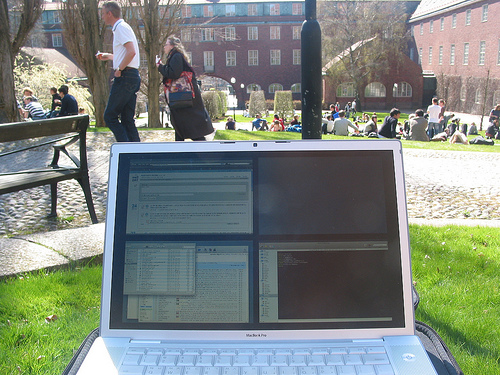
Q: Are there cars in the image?
A: No, there are no cars.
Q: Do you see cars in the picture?
A: No, there are no cars.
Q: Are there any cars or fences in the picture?
A: No, there are no cars or fences.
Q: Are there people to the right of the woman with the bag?
A: Yes, there is a person to the right of the woman.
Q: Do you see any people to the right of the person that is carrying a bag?
A: Yes, there is a person to the right of the woman.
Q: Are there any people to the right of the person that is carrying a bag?
A: Yes, there is a person to the right of the woman.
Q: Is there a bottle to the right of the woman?
A: No, there is a person to the right of the woman.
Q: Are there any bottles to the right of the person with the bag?
A: No, there is a person to the right of the woman.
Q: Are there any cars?
A: No, there are no cars.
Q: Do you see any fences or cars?
A: No, there are no cars or fences.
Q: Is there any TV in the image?
A: No, there are no televisions.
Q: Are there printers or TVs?
A: No, there are no TVs or printers.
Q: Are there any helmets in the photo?
A: No, there are no helmets.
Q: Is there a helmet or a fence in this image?
A: No, there are no helmets or fences.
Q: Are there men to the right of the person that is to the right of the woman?
A: Yes, there is a man to the right of the person.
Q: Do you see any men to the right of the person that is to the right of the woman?
A: Yes, there is a man to the right of the person.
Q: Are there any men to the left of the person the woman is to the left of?
A: No, the man is to the right of the person.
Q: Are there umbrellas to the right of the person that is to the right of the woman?
A: No, there is a man to the right of the person.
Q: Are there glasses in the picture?
A: No, there are no glasses.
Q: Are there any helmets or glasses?
A: No, there are no glasses or helmets.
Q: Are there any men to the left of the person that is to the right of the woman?
A: No, the man is to the right of the person.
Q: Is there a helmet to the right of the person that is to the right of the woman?
A: No, there is a man to the right of the person.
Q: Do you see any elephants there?
A: Yes, there is an elephant.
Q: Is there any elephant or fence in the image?
A: Yes, there is an elephant.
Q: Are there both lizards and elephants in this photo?
A: No, there is an elephant but no lizards.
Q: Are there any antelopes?
A: No, there are no antelopes.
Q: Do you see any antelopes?
A: No, there are no antelopes.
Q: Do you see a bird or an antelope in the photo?
A: No, there are no antelopes or birds.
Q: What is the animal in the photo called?
A: The animal is an elephant.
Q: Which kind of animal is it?
A: The animal is an elephant.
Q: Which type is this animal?
A: This is an elephant.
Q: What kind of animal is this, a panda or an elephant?
A: This is an elephant.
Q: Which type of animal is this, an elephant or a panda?
A: This is an elephant.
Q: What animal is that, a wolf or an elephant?
A: That is an elephant.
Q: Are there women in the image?
A: Yes, there is a woman.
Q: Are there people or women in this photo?
A: Yes, there is a woman.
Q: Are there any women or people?
A: Yes, there is a woman.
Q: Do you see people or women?
A: Yes, there is a woman.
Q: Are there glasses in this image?
A: No, there are no glasses.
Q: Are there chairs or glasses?
A: No, there are no glasses or chairs.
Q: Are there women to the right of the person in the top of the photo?
A: Yes, there is a woman to the right of the person.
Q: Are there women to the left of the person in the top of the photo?
A: No, the woman is to the right of the person.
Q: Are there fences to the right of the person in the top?
A: No, there is a woman to the right of the person.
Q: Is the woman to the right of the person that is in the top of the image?
A: Yes, the woman is to the right of the person.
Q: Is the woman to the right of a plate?
A: No, the woman is to the right of the person.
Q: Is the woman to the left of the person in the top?
A: No, the woman is to the right of the person.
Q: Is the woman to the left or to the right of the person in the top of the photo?
A: The woman is to the right of the person.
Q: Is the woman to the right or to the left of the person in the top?
A: The woman is to the right of the person.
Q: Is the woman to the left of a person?
A: Yes, the woman is to the left of a person.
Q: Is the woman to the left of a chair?
A: No, the woman is to the left of a person.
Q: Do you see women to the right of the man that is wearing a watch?
A: Yes, there is a woman to the right of the man.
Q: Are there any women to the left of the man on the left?
A: No, the woman is to the right of the man.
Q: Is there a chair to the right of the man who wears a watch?
A: No, there is a woman to the right of the man.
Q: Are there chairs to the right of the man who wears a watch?
A: No, there is a woman to the right of the man.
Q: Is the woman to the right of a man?
A: Yes, the woman is to the right of a man.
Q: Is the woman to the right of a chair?
A: No, the woman is to the right of a man.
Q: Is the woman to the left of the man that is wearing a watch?
A: No, the woman is to the right of the man.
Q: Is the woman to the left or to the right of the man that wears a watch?
A: The woman is to the right of the man.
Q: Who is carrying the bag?
A: The woman is carrying the bag.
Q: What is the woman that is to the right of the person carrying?
A: The woman is carrying a bag.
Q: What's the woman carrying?
A: The woman is carrying a bag.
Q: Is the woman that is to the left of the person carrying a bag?
A: Yes, the woman is carrying a bag.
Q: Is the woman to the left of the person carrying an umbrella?
A: No, the woman is carrying a bag.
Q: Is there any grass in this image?
A: Yes, there is grass.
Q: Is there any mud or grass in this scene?
A: Yes, there is grass.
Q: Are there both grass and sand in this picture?
A: No, there is grass but no sand.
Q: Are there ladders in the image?
A: No, there are no ladders.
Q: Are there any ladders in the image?
A: No, there are no ladders.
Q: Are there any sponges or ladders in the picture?
A: No, there are no ladders or sponges.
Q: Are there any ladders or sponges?
A: No, there are no ladders or sponges.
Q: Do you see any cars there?
A: No, there are no cars.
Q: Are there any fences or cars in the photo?
A: No, there are no cars or fences.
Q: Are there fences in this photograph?
A: No, there are no fences.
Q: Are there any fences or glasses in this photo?
A: No, there are no fences or glasses.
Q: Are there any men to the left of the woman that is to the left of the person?
A: Yes, there is a man to the left of the woman.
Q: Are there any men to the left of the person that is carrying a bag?
A: Yes, there is a man to the left of the woman.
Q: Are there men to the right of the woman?
A: No, the man is to the left of the woman.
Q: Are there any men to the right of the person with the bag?
A: No, the man is to the left of the woman.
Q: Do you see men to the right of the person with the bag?
A: No, the man is to the left of the woman.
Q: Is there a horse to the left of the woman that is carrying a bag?
A: No, there is a man to the left of the woman.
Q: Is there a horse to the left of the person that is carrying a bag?
A: No, there is a man to the left of the woman.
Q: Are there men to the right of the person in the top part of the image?
A: Yes, there is a man to the right of the person.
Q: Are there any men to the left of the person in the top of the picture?
A: No, the man is to the right of the person.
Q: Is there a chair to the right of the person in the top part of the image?
A: No, there is a man to the right of the person.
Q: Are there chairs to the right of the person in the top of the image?
A: No, there is a man to the right of the person.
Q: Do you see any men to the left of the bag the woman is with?
A: Yes, there is a man to the left of the bag.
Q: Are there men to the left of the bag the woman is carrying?
A: Yes, there is a man to the left of the bag.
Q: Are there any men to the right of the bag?
A: No, the man is to the left of the bag.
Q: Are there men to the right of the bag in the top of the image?
A: No, the man is to the left of the bag.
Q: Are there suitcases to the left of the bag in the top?
A: No, there is a man to the left of the bag.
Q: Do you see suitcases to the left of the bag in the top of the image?
A: No, there is a man to the left of the bag.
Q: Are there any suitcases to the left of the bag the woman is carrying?
A: No, there is a man to the left of the bag.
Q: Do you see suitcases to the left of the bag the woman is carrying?
A: No, there is a man to the left of the bag.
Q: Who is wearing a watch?
A: The man is wearing a watch.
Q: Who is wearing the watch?
A: The man is wearing a watch.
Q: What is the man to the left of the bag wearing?
A: The man is wearing a watch.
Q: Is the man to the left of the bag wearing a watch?
A: Yes, the man is wearing a watch.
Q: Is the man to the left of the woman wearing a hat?
A: No, the man is wearing a watch.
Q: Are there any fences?
A: No, there are no fences.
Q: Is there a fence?
A: No, there are no fences.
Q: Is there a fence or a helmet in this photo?
A: No, there are no fences or helmets.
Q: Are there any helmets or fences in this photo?
A: No, there are no fences or helmets.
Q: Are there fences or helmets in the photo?
A: No, there are no fences or helmets.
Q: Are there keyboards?
A: Yes, there is a keyboard.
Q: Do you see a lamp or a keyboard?
A: Yes, there is a keyboard.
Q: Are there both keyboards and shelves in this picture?
A: No, there is a keyboard but no shelves.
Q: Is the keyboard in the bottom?
A: Yes, the keyboard is in the bottom of the image.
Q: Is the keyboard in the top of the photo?
A: No, the keyboard is in the bottom of the image.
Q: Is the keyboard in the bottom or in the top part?
A: The keyboard is in the bottom of the image.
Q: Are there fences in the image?
A: No, there are no fences.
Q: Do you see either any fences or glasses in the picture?
A: No, there are no fences or glasses.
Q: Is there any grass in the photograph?
A: Yes, there is grass.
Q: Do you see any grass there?
A: Yes, there is grass.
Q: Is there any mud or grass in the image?
A: Yes, there is grass.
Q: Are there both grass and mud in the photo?
A: No, there is grass but no mud.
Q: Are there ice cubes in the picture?
A: No, there are no ice cubes.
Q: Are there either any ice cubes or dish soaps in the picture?
A: No, there are no ice cubes or dish soaps.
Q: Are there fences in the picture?
A: No, there are no fences.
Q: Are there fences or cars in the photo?
A: No, there are no fences or cars.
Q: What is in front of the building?
A: The tree is in front of the building.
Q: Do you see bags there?
A: Yes, there is a bag.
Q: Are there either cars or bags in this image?
A: Yes, there is a bag.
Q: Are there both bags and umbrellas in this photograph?
A: No, there is a bag but no umbrellas.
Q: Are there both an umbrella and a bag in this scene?
A: No, there is a bag but no umbrellas.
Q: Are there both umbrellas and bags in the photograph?
A: No, there is a bag but no umbrellas.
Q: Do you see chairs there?
A: No, there are no chairs.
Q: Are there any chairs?
A: No, there are no chairs.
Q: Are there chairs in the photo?
A: No, there are no chairs.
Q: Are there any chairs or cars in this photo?
A: No, there are no chairs or cars.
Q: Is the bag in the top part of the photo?
A: Yes, the bag is in the top of the image.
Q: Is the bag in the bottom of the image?
A: No, the bag is in the top of the image.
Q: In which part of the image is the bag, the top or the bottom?
A: The bag is in the top of the image.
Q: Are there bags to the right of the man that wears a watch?
A: Yes, there is a bag to the right of the man.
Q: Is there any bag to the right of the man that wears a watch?
A: Yes, there is a bag to the right of the man.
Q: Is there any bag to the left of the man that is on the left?
A: No, the bag is to the right of the man.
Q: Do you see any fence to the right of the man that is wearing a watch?
A: No, there is a bag to the right of the man.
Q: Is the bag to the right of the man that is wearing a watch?
A: Yes, the bag is to the right of the man.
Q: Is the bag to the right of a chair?
A: No, the bag is to the right of the man.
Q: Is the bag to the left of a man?
A: No, the bag is to the right of a man.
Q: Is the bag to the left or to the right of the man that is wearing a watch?
A: The bag is to the right of the man.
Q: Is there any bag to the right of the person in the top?
A: Yes, there is a bag to the right of the person.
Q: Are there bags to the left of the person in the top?
A: No, the bag is to the right of the person.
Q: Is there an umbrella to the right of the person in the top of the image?
A: No, there is a bag to the right of the person.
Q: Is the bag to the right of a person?
A: Yes, the bag is to the right of a person.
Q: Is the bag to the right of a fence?
A: No, the bag is to the right of a person.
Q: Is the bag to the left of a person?
A: No, the bag is to the right of a person.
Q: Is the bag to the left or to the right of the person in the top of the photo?
A: The bag is to the right of the person.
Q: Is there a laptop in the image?
A: Yes, there is a laptop.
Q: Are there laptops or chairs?
A: Yes, there is a laptop.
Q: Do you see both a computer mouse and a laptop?
A: No, there is a laptop but no computer mice.